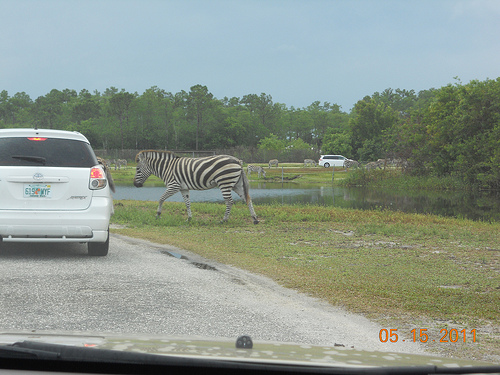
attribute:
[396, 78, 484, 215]
tree — green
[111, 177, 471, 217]
water — still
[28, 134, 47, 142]
light — red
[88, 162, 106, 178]
light — red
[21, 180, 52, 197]
plates — white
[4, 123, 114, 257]
car — white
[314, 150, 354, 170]
car — white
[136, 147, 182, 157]
mane — white and black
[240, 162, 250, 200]
tail — long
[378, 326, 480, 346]
date — orange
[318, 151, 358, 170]
van — white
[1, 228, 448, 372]
road — gravel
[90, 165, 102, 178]
brake light — red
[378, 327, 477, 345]
time stamp — orange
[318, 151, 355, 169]
vehicle — white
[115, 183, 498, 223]
water — small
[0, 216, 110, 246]
car bumper — white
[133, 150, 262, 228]
zebra — black and white, striped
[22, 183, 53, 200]
license plate — Florida, white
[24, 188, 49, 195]
writing — green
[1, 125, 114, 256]
van — white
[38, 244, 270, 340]
road — light grey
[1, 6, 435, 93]
sky — hazy, light blue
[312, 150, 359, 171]
van — white